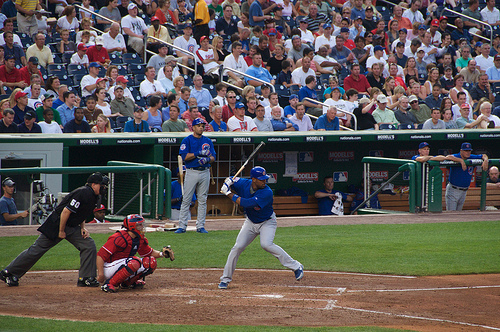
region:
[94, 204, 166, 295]
baseball catcher wearing red and white uniform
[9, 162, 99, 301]
baseball umpire leaning forward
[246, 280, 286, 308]
home plate on baseball field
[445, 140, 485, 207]
man in blue hat and shirt leaning over rail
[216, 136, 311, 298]
man in blue and grey uniform at bat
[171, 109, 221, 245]
man waiting on deck to bat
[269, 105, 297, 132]
man with arms crossed in stands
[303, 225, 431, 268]
green grass of the baseball field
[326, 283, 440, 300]
white chalk lines on baseball field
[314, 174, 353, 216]
man sitting on bench with towel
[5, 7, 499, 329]
a baseball match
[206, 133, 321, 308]
baseball player swinging his bat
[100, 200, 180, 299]
catcher wearing a red uniform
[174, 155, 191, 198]
man holding a white baseball bat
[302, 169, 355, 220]
man sitting on a wooden bench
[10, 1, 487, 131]
spectators watching a baseball match in the bleachers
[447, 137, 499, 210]
man with his arms propped on a fence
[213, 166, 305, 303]
baseball player with a blue and white uniform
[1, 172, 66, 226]
a cameraman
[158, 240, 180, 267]
a leather catcher's mitt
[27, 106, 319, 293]
the player is ready to swing the bat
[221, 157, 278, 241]
this team is wearing blue jerseys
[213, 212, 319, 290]
their pants are grey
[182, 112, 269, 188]
their helmets are blue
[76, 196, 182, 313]
the catcher is wearing a red jersey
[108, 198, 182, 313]
his shin guards are red as well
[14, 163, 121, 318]
the umpire is leaned in to make the call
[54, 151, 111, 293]
the umpire is wearing a black shirt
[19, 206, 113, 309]
his pants are grey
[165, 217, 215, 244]
this player is has blue spikes on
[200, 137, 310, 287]
Batter preparing to hit the ball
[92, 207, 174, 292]
Catcher in full gear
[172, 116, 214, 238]
Batter on deck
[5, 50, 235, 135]
Fans sitting in bleachers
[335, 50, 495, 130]
People watching a baseball game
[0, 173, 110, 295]
Umpire leaning in to watch the ball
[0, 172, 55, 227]
Camera man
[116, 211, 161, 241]
Red catchers face mask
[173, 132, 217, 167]
Blue red and whit baseball jersey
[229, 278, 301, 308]
White home plate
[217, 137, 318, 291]
a baseball player swinging a bat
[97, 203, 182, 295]
a baseball catcher calling the calls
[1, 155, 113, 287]
an umpire officiating a game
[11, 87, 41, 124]
man wearing a blue shirt and red hat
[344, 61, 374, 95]
a man wearing red shirt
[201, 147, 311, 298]
a man wearing blue shoes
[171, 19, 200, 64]
a man wearing a cubs shirt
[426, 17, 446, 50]
a man wearing a red hat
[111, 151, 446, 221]
an open gate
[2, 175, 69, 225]
camera man operating a camera